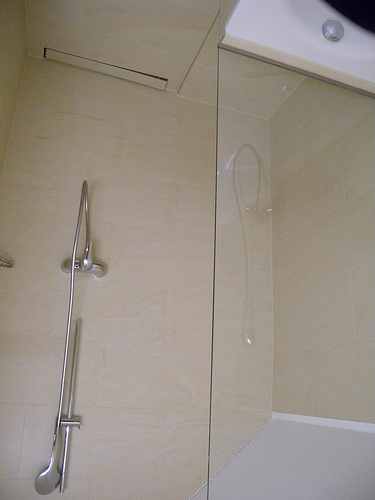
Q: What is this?
A: A shower.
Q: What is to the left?
A: A bench.